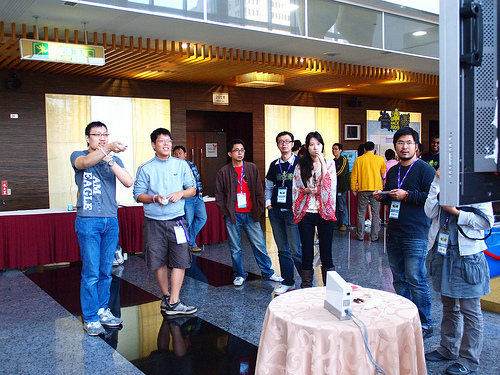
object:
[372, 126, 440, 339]
person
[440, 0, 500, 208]
tv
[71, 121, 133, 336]
man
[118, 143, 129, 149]
remote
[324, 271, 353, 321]
wii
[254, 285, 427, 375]
table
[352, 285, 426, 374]
tablecloth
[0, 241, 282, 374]
floor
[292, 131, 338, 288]
woman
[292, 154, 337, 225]
sweater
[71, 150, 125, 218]
shirt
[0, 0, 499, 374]
photo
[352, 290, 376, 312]
sheet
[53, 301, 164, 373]
reflection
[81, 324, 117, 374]
reflection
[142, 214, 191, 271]
shorts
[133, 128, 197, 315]
person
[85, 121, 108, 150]
head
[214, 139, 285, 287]
man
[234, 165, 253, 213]
shirt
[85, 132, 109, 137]
glasses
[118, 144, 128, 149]
game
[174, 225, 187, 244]
tag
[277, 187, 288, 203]
tag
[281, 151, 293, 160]
neck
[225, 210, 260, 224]
pocket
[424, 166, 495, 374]
woman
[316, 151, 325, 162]
hand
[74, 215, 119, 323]
jeans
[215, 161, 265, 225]
jacket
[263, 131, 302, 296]
man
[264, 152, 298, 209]
sweater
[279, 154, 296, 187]
lanyard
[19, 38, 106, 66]
sign